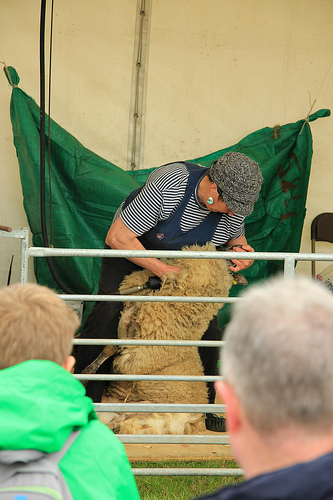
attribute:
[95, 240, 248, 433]
sheep — brown wooled, being sheared, white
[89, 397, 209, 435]
wool — brown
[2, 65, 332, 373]
tarp — large, hanging, green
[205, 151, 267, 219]
hat — grey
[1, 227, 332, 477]
gate — metal, large, grey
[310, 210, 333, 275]
chair — folding, black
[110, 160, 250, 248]
shirt — striped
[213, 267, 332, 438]
hair — grey, white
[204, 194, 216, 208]
earring — beautiful, silver, shiny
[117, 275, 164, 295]
shear — black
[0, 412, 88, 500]
backpack — zipped, gray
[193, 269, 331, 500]
man — old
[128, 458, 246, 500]
grass — green, short, green in color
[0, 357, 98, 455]
hood — green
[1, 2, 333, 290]
wall — white, clean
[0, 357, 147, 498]
jacket — green